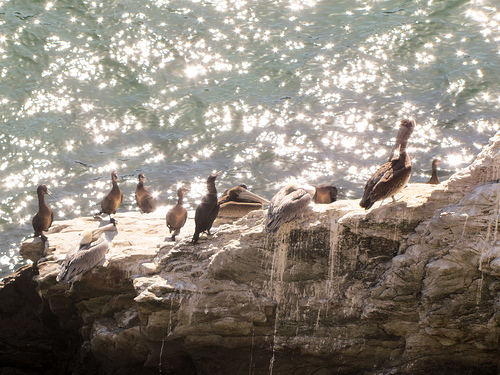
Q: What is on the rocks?
A: Birds.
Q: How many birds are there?
A: 11.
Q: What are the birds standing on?
A: Rocks.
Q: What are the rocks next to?
A: The water.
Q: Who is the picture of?
A: The birds.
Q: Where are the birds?
A: On the rocks.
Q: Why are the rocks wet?
A: They are by the water.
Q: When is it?
A: Day time.